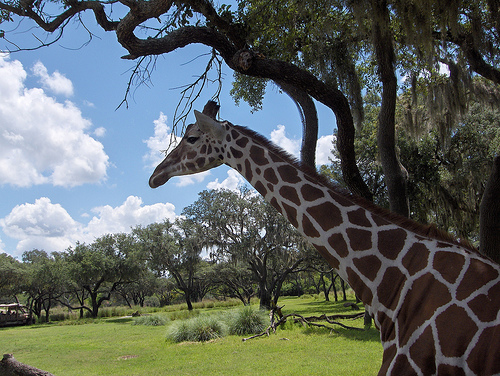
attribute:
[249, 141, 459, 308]
neck — long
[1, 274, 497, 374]
field — green, grassy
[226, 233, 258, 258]
leaves — green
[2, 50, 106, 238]
clouds — white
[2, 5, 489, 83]
sky — blue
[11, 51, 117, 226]
sky — blue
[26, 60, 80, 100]
cloud — white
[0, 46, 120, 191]
cloud — white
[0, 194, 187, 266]
cloud — white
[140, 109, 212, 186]
cloud — white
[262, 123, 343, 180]
cloud — white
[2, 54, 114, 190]
cloud — white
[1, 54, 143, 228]
clouds — white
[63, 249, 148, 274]
leaves — green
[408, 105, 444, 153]
leaves — green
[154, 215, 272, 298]
trees — green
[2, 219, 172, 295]
leaves — green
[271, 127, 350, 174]
cloud — white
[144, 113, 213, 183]
cloud — white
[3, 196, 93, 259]
cloud — white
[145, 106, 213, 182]
cloud — white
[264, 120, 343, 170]
cloud — white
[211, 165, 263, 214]
cloud — white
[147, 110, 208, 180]
cloud — white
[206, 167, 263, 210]
cloud — white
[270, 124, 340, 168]
cloud — white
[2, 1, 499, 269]
sky — blue, white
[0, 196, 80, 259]
cloud — white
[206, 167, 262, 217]
cloud — white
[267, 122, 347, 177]
cloud — white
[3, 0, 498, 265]
clouds — white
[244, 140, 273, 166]
spot — brown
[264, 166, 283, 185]
spot — brown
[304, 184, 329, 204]
spot — brown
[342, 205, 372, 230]
spot — brown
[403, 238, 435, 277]
spot — brown